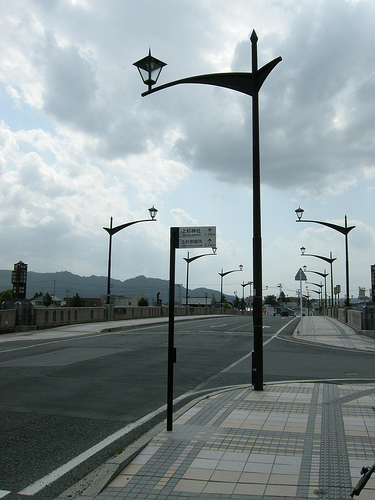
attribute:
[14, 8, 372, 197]
skies — cloudy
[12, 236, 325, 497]
street — dark grey, empty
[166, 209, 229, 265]
sign — traffic control, grey, white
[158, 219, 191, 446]
pole — black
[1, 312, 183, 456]
pavement — asphalt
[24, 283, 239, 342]
area — populated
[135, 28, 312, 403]
street lamp — off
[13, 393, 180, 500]
line — white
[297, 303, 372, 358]
crosswalk — pedestrians, tailed